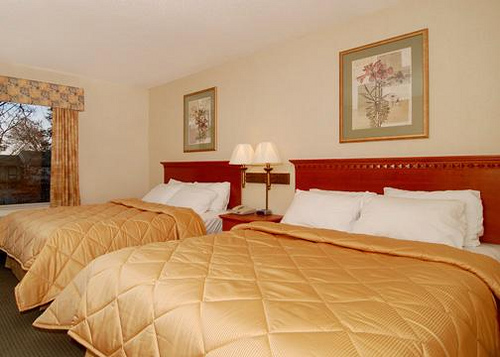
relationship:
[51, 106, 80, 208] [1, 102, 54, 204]
drape hanging on window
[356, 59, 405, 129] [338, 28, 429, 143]
flowers in middle of picture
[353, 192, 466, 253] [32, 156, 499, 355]
pillow on top of bed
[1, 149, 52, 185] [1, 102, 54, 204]
house outside of window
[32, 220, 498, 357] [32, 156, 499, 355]
comforter on top of bed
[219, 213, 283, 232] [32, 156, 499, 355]
end table next to bed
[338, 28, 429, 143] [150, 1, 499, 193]
picture hanging on wall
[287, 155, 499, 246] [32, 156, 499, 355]
headboard behind bed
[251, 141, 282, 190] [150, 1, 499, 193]
lamp hanging on wall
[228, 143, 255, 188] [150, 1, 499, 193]
lamp hanging on wall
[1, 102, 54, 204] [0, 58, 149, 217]
window on side of wall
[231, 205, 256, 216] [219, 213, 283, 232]
phone on top of end table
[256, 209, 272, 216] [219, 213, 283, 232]
clock on top of end table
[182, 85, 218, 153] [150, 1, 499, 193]
picture hanging on wall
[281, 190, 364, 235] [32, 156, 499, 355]
pillow on top of bed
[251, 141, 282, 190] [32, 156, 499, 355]
lamp next to bed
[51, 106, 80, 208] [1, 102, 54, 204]
drape next to window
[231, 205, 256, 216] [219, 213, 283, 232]
phone sitting on end table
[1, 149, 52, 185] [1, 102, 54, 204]
house visible through window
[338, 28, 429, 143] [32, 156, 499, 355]
picture above bed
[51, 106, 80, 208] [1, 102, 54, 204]
drape alongside window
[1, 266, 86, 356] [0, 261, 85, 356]
carpet on top of floor